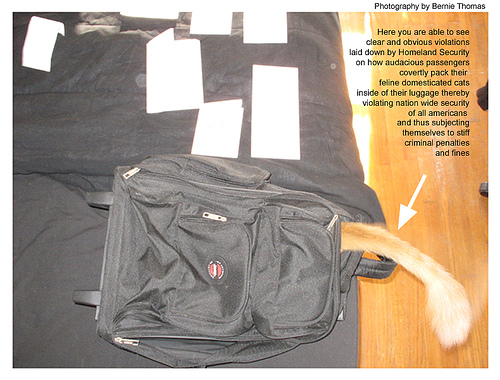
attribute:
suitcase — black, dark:
[72, 155, 341, 369]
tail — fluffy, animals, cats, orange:
[340, 222, 472, 348]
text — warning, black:
[347, 28, 470, 158]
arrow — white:
[397, 172, 427, 230]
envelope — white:
[251, 63, 301, 160]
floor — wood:
[336, 11, 489, 368]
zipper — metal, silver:
[123, 167, 140, 179]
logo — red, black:
[206, 255, 227, 282]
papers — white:
[145, 28, 245, 161]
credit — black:
[375, 1, 487, 11]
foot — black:
[72, 289, 104, 309]